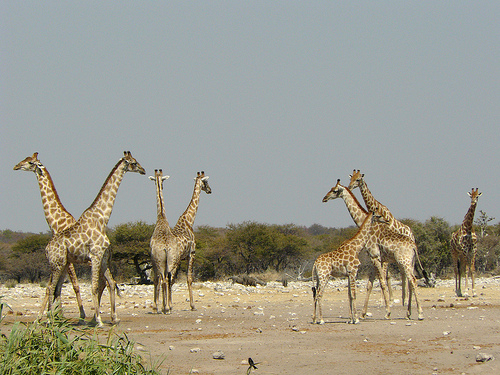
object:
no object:
[213, 82, 355, 176]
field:
[0, 276, 499, 374]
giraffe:
[323, 171, 430, 320]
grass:
[21, 319, 111, 371]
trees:
[159, 216, 329, 272]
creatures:
[310, 209, 377, 324]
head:
[121, 150, 146, 175]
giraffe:
[44, 150, 146, 326]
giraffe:
[157, 164, 215, 311]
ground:
[0, 279, 500, 374]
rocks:
[240, 297, 278, 321]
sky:
[0, 0, 500, 234]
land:
[164, 270, 408, 356]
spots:
[320, 248, 352, 281]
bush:
[0, 311, 157, 374]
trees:
[208, 210, 291, 277]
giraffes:
[347, 169, 421, 315]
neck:
[89, 156, 128, 224]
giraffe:
[13, 145, 121, 326]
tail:
[305, 275, 332, 305]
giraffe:
[310, 211, 388, 325]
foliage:
[8, 303, 116, 373]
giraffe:
[311, 210, 392, 325]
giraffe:
[448, 187, 484, 298]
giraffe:
[14, 151, 122, 326]